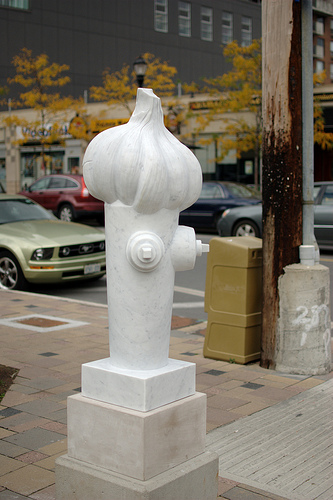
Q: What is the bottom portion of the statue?
A: Fire hydrant.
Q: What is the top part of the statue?
A: Garlic.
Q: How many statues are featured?
A: 1.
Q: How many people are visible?
A: Zero.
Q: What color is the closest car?
A: Green.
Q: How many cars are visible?
A: 4.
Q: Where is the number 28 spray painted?
A: Concrete base.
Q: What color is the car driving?
A: Grey.